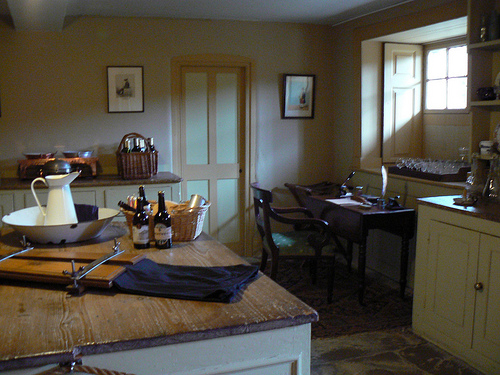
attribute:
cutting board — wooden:
[0, 241, 149, 294]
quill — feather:
[375, 163, 391, 208]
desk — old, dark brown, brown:
[297, 189, 419, 310]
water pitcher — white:
[28, 168, 87, 225]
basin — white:
[0, 200, 123, 247]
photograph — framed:
[103, 63, 148, 116]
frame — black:
[279, 70, 318, 121]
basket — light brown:
[114, 194, 214, 244]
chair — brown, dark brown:
[243, 176, 340, 309]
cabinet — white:
[407, 201, 499, 374]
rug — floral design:
[242, 248, 415, 341]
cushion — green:
[260, 223, 341, 262]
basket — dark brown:
[113, 129, 163, 182]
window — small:
[419, 43, 467, 111]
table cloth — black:
[110, 255, 264, 305]